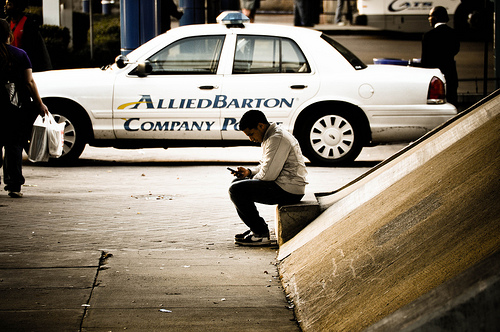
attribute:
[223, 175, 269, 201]
knees — BENT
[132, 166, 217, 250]
ground — WHITE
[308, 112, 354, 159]
rims — silver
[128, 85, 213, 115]
wrtitng — blue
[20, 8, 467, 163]
car — white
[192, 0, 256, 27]
lights — blue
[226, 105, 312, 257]
man — light skinned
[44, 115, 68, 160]
bag — paper